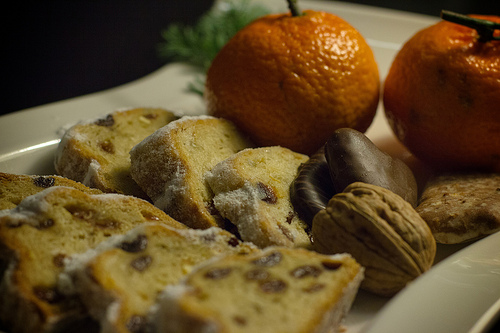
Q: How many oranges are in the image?
A: Two.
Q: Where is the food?
A: On a plate.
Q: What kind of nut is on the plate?
A: Walnut.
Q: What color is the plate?
A: White.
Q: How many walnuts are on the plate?
A: One.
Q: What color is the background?
A: Black.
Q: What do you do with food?
A: Eat it.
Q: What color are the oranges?
A: Orange.